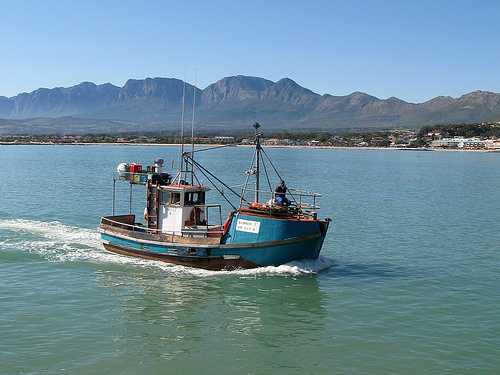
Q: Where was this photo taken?
A: On a river.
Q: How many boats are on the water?
A: One.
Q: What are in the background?
A: Mountain.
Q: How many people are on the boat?
A: One.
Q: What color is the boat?
A: Blue.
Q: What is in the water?
A: A boat.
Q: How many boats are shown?
A: One.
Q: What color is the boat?
A: Blue.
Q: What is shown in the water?
A: A reflection.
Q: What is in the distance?
A: Mountains.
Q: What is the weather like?
A: Sunny.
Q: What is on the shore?
A: Buildings.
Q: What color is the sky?
A: Blue.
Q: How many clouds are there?
A: Zero.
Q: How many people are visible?
A: One.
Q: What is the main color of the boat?
A: Turquoise.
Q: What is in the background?
A: Mountains.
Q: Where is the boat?
A: On the water.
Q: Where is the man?
A: On the front of the boat.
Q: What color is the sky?
A: Blue.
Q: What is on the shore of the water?
A: City.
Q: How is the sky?
A: Clear.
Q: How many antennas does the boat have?
A: Two.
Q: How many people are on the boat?
A: One.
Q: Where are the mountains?
A: Behind the boat.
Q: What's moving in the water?
A: A boat.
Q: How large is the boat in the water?
A: Small.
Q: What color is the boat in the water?
A: Blue.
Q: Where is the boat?
A: On water.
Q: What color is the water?
A: Bluish green.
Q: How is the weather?
A: Sunny.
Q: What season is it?
A: Spring.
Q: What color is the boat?
A: Blue.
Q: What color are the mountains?
A: Brown.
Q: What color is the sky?
A: Blue.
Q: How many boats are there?
A: One.